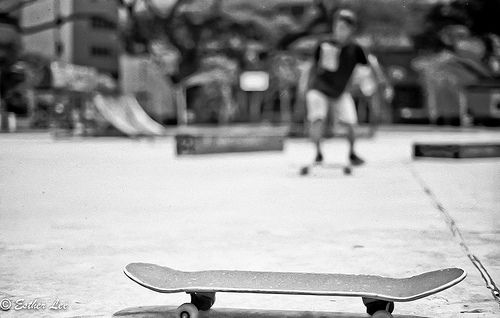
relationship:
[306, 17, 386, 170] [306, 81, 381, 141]
man wearing shorts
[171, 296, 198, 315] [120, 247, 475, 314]
wheel on skateboard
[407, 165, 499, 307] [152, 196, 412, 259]
lines on ground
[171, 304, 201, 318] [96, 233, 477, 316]
wheel on skateboad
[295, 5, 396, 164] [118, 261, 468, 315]
boy riding skateboard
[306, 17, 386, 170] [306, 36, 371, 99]
man has shirt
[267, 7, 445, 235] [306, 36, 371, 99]
skateboarder wearing shirt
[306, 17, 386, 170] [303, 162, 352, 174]
man on skateboard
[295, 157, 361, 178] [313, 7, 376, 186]
skateboard with man